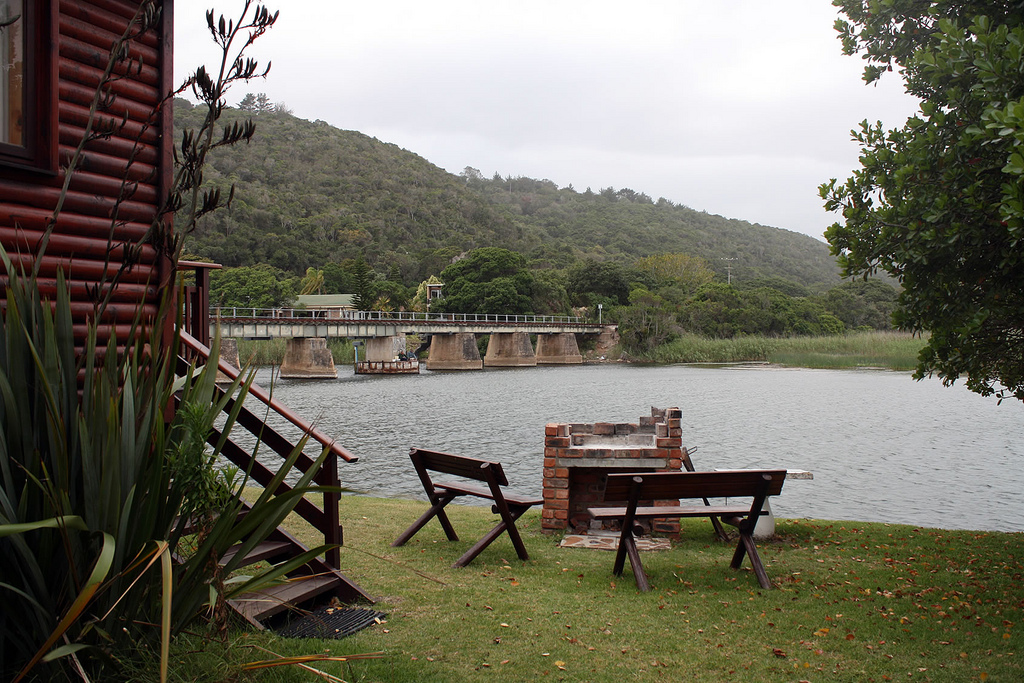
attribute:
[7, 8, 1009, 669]
scene — outdoors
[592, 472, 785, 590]
bench — brown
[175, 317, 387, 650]
stairs — slanted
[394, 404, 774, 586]
fireplace — brick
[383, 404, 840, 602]
oven — small, brick